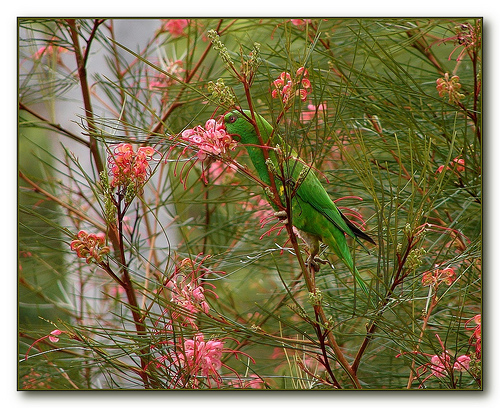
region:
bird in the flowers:
[179, 88, 355, 243]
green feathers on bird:
[276, 108, 369, 215]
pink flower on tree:
[99, 131, 179, 199]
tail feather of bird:
[311, 240, 391, 309]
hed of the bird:
[206, 105, 258, 152]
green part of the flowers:
[330, 42, 421, 137]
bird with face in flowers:
[164, 90, 356, 288]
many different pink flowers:
[91, 113, 238, 363]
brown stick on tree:
[62, 40, 116, 150]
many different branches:
[30, 45, 457, 374]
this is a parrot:
[240, 117, 336, 262]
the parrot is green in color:
[302, 190, 320, 214]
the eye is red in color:
[227, 114, 238, 123]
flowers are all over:
[128, 272, 345, 388]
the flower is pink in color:
[193, 125, 224, 157]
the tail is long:
[350, 258, 367, 300]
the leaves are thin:
[371, 75, 418, 126]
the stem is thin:
[333, 345, 365, 377]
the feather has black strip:
[351, 225, 369, 239]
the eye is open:
[228, 114, 239, 124]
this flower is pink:
[95, 119, 166, 210]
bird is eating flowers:
[150, 64, 407, 326]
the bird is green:
[156, 72, 399, 308]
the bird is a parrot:
[145, 75, 422, 300]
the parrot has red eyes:
[174, 77, 410, 303]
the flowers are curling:
[64, 110, 189, 237]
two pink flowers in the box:
[49, 122, 161, 284]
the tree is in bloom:
[123, 37, 449, 347]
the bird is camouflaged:
[114, 66, 459, 356]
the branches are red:
[141, 80, 398, 332]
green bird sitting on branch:
[207, 75, 382, 310]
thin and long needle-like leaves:
[355, 101, 437, 312]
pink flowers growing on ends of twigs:
[70, 122, 221, 377]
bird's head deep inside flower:
[200, 95, 260, 155]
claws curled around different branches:
[262, 200, 327, 290]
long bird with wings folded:
[211, 90, 391, 310]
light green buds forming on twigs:
[381, 206, 431, 291]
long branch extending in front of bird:
[205, 65, 375, 355]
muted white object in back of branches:
[17, 20, 192, 365]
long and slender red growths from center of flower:
[118, 308, 263, 383]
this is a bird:
[211, 109, 371, 275]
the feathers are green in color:
[304, 189, 326, 234]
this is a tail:
[312, 196, 379, 305]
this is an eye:
[226, 112, 238, 124]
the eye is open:
[226, 110, 241, 127]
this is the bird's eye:
[204, 107, 274, 141]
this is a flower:
[180, 121, 220, 149]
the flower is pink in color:
[193, 130, 215, 145]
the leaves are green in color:
[328, 285, 415, 326]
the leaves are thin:
[399, 110, 430, 175]